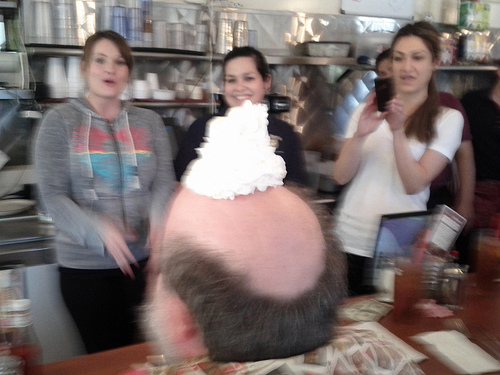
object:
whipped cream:
[180, 100, 288, 201]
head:
[135, 184, 347, 360]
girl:
[34, 30, 177, 354]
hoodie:
[34, 98, 176, 269]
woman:
[330, 20, 467, 293]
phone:
[374, 78, 396, 112]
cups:
[43, 57, 87, 99]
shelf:
[32, 98, 221, 111]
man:
[126, 188, 428, 375]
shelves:
[22, 2, 500, 195]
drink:
[394, 262, 421, 322]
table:
[19, 270, 499, 374]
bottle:
[0, 298, 44, 373]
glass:
[394, 255, 431, 321]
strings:
[84, 113, 139, 178]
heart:
[73, 125, 153, 194]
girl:
[330, 21, 463, 297]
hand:
[384, 99, 408, 130]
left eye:
[114, 59, 126, 65]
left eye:
[412, 54, 424, 61]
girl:
[174, 46, 309, 193]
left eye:
[244, 75, 254, 81]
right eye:
[94, 58, 105, 64]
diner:
[3, 1, 498, 374]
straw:
[415, 229, 432, 268]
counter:
[41, 274, 498, 374]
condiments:
[0, 295, 44, 374]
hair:
[389, 20, 442, 143]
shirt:
[330, 103, 465, 259]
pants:
[56, 257, 149, 355]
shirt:
[175, 113, 312, 190]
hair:
[224, 46, 269, 82]